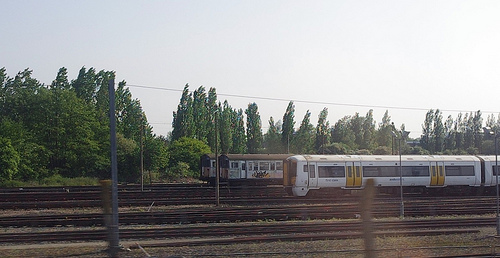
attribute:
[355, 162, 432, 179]
window — passenger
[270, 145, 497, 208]
train — white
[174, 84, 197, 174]
tree — tall, green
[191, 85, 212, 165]
tree — tall, green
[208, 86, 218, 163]
tree — tall, green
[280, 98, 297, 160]
tree — tall, green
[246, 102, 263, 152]
tree — tall, green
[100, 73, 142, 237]
pole — grey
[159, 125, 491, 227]
train — white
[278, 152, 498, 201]
train — white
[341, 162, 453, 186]
doors — yellow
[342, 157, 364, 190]
door — yellow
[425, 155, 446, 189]
door — yellow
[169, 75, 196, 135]
tree — pine, large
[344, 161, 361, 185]
train doors — white, yellow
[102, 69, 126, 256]
pole — grey, metal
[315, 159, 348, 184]
window — passenger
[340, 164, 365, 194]
doors — yellow